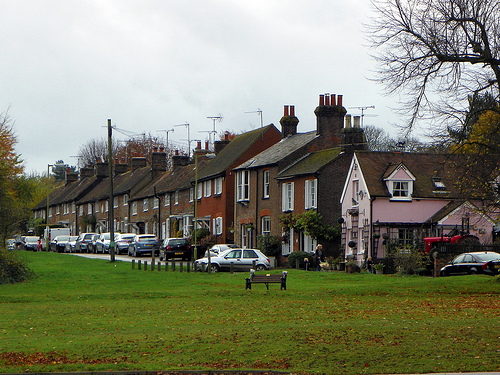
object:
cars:
[95, 232, 120, 253]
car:
[159, 237, 191, 261]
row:
[42, 189, 377, 260]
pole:
[193, 153, 199, 263]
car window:
[225, 250, 241, 259]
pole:
[105, 119, 117, 262]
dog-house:
[382, 161, 417, 202]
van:
[42, 227, 70, 250]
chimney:
[344, 114, 364, 144]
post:
[138, 260, 142, 270]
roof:
[340, 145, 500, 202]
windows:
[262, 169, 271, 198]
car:
[194, 246, 272, 273]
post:
[132, 259, 136, 269]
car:
[128, 234, 161, 257]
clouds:
[0, 0, 500, 169]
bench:
[245, 269, 288, 290]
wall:
[199, 203, 224, 214]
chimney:
[314, 93, 347, 136]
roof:
[188, 104, 299, 184]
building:
[340, 149, 500, 271]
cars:
[109, 233, 136, 254]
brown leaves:
[0, 285, 499, 375]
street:
[0, 231, 499, 274]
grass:
[0, 247, 500, 375]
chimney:
[278, 104, 300, 137]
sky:
[0, 0, 500, 178]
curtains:
[393, 182, 409, 196]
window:
[214, 176, 221, 194]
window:
[305, 179, 317, 209]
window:
[263, 171, 270, 198]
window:
[282, 183, 294, 212]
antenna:
[52, 104, 378, 176]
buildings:
[75, 146, 166, 257]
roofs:
[127, 134, 231, 204]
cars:
[440, 251, 500, 278]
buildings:
[75, 151, 147, 234]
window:
[382, 165, 420, 202]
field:
[0, 246, 500, 375]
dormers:
[388, 223, 441, 250]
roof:
[231, 94, 346, 173]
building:
[271, 92, 352, 264]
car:
[204, 243, 240, 258]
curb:
[72, 253, 139, 265]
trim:
[316, 143, 449, 329]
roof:
[273, 114, 369, 180]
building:
[193, 105, 297, 257]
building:
[129, 134, 231, 260]